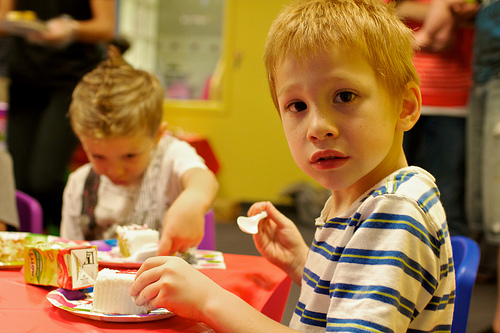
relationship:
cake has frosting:
[84, 264, 155, 317] [95, 268, 138, 284]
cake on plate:
[84, 264, 155, 317] [44, 285, 180, 328]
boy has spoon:
[240, 7, 461, 323] [228, 205, 276, 236]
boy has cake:
[240, 7, 461, 323] [84, 264, 155, 317]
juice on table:
[17, 237, 104, 292] [5, 238, 289, 326]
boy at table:
[240, 7, 461, 323] [5, 238, 289, 326]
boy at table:
[37, 48, 223, 246] [5, 238, 289, 326]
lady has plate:
[4, 3, 97, 217] [8, 10, 48, 35]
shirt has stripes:
[288, 174, 457, 329] [340, 239, 446, 286]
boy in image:
[240, 7, 461, 323] [4, 7, 490, 322]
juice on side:
[17, 237, 104, 292] [27, 275, 88, 295]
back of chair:
[458, 231, 483, 280] [448, 228, 484, 332]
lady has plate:
[4, 3, 97, 217] [44, 285, 180, 328]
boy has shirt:
[240, 7, 461, 323] [288, 174, 457, 329]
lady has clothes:
[4, 3, 97, 217] [10, 7, 79, 161]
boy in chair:
[240, 7, 461, 323] [448, 228, 484, 332]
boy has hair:
[240, 7, 461, 323] [266, 11, 411, 72]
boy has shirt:
[37, 48, 223, 246] [60, 145, 200, 231]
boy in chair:
[37, 48, 223, 246] [197, 212, 224, 251]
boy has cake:
[37, 48, 223, 246] [109, 221, 159, 256]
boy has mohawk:
[37, 48, 223, 246] [86, 45, 131, 134]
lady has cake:
[4, 3, 97, 217] [7, 8, 41, 20]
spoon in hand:
[228, 205, 276, 236] [253, 202, 299, 272]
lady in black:
[4, 3, 97, 217] [9, 8, 88, 159]